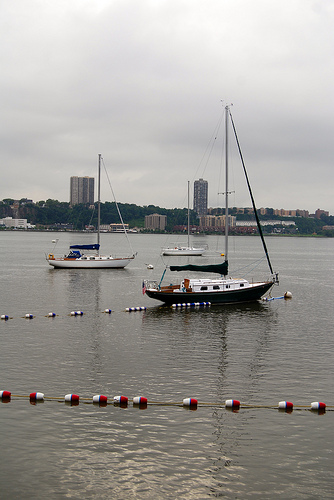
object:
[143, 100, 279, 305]
boat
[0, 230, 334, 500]
water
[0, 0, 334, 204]
sky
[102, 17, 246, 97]
cloud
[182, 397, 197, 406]
buoy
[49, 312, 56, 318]
buoy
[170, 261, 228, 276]
sail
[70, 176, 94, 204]
building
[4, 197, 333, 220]
skyline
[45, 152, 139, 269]
boat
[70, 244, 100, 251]
sail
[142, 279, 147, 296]
flag